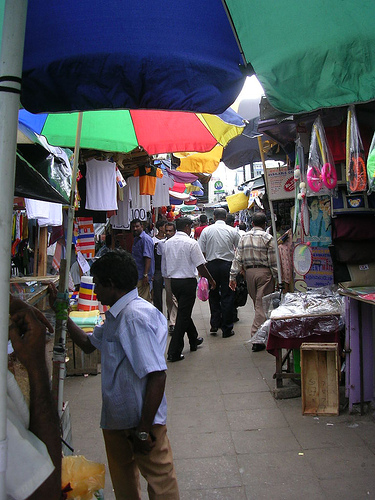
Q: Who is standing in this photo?
A: Men.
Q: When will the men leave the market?
A: After they have finished shopping.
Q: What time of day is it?
A: Daytime.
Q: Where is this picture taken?
A: At a flea market.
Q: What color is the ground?
A: Gray.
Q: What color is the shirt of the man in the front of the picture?
A: White.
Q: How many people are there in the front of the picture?
A: One.